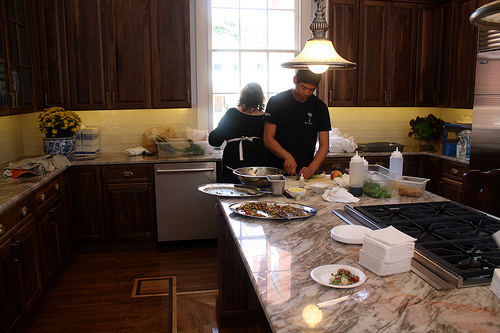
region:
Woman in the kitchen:
[207, 80, 267, 182]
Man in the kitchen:
[259, 69, 331, 180]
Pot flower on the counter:
[36, 104, 81, 159]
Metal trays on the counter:
[195, 182, 316, 222]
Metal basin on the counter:
[232, 165, 284, 190]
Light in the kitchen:
[279, 2, 359, 74]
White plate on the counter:
[310, 264, 367, 289]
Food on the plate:
[327, 266, 359, 287]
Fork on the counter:
[316, 282, 376, 309]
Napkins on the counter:
[357, 225, 417, 277]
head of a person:
[287, 59, 321, 103]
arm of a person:
[252, 125, 307, 159]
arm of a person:
[307, 118, 341, 170]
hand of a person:
[270, 162, 310, 182]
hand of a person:
[300, 161, 321, 182]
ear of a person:
[289, 71, 306, 88]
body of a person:
[260, 93, 340, 154]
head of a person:
[229, 76, 277, 118]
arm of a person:
[202, 106, 236, 153]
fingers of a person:
[282, 165, 302, 179]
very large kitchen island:
[220, 173, 497, 331]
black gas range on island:
[346, 204, 498, 282]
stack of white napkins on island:
[357, 226, 414, 276]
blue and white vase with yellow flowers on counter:
[39, 107, 81, 159]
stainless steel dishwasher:
[153, 163, 219, 243]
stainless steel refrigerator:
[465, 53, 497, 213]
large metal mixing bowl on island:
[230, 165, 282, 187]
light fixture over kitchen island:
[283, 1, 357, 75]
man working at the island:
[264, 68, 329, 177]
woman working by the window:
[210, 83, 282, 180]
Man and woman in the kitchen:
[208, 66, 332, 177]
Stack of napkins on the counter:
[359, 224, 416, 281]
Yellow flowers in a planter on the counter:
[36, 104, 81, 160]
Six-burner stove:
[343, 197, 498, 294]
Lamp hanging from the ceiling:
[279, 0, 357, 75]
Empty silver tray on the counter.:
[198, 179, 260, 196]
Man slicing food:
[262, 68, 333, 179]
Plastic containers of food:
[361, 162, 429, 198]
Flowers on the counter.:
[405, 110, 445, 153]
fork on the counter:
[307, 286, 370, 311]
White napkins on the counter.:
[367, 226, 406, 287]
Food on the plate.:
[332, 264, 349, 291]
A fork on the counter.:
[288, 279, 396, 321]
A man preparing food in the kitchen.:
[229, 51, 347, 169]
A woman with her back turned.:
[221, 82, 285, 167]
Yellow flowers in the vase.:
[41, 107, 87, 135]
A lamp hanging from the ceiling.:
[275, 7, 350, 88]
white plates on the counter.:
[329, 228, 381, 255]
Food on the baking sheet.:
[246, 196, 298, 216]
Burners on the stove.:
[403, 202, 493, 271]